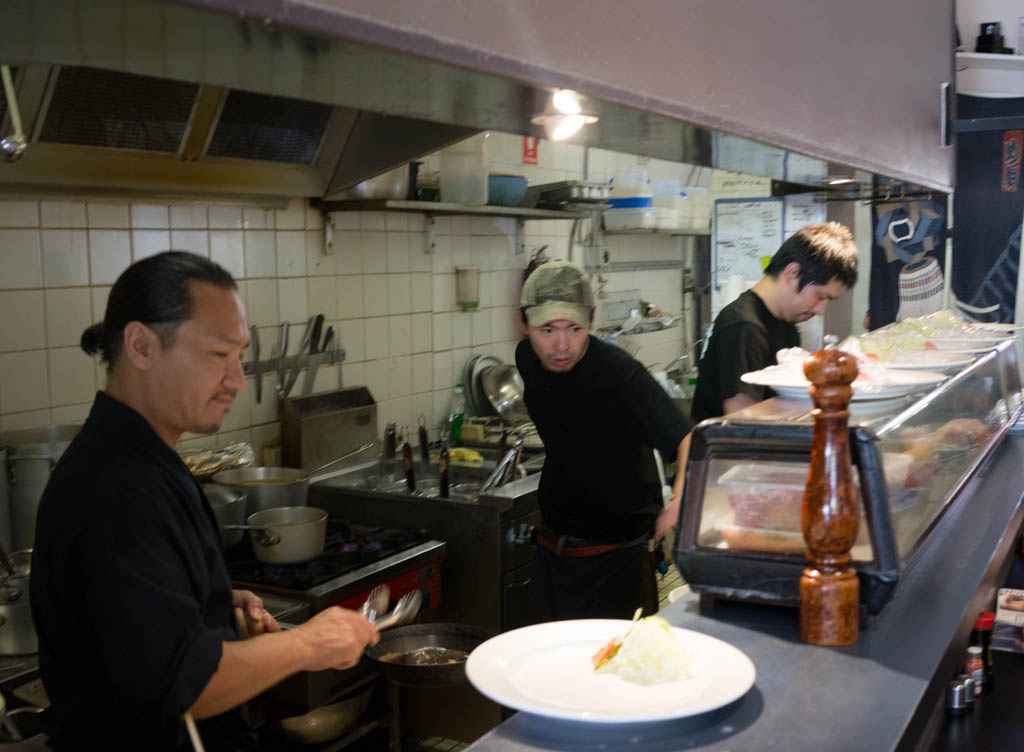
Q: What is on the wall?
A: White tiles.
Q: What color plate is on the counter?
A: White.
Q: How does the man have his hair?
A: In a ponytail.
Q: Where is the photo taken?
A: In a kitchen.